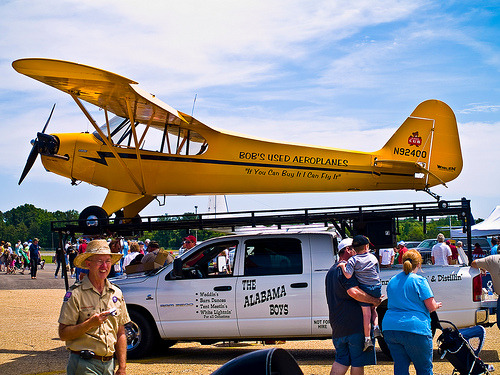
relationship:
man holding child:
[324, 236, 385, 375] [337, 235, 383, 351]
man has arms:
[324, 236, 385, 375] [347, 288, 385, 307]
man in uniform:
[58, 238, 133, 375] [59, 276, 131, 359]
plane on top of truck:
[11, 58, 462, 228] [106, 227, 490, 360]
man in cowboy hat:
[58, 238, 133, 375] [72, 238, 123, 271]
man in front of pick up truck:
[58, 238, 133, 375] [106, 227, 490, 360]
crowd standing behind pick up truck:
[53, 234, 203, 277] [106, 227, 490, 360]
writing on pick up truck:
[239, 277, 289, 317] [106, 227, 490, 360]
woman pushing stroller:
[382, 249, 443, 374] [437, 316, 496, 375]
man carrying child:
[324, 236, 385, 375] [337, 235, 383, 351]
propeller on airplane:
[15, 101, 58, 184] [11, 58, 462, 228]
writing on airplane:
[237, 151, 350, 169] [11, 58, 462, 228]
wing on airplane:
[12, 58, 222, 135] [11, 58, 462, 228]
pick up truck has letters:
[106, 227, 490, 360] [239, 277, 289, 317]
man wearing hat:
[58, 238, 133, 375] [72, 238, 123, 271]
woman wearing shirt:
[382, 249, 443, 374] [381, 269, 435, 336]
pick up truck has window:
[106, 227, 490, 360] [163, 239, 239, 281]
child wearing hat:
[337, 235, 383, 351] [352, 233, 375, 250]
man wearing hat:
[180, 235, 204, 267] [184, 233, 197, 243]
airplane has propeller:
[11, 58, 462, 228] [15, 101, 58, 184]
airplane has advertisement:
[11, 58, 462, 228] [238, 148, 350, 180]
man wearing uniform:
[58, 238, 133, 375] [59, 276, 131, 359]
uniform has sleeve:
[59, 276, 131, 359] [58, 289, 81, 326]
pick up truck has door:
[106, 227, 490, 360] [154, 236, 240, 342]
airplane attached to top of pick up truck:
[11, 58, 462, 228] [106, 227, 490, 360]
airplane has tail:
[11, 58, 462, 228] [371, 100, 462, 191]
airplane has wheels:
[11, 58, 462, 228] [76, 205, 143, 230]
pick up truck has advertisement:
[106, 227, 490, 360] [158, 277, 290, 320]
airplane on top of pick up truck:
[11, 58, 462, 228] [106, 227, 490, 360]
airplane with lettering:
[11, 58, 462, 228] [237, 151, 350, 169]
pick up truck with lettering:
[106, 227, 490, 360] [239, 277, 289, 317]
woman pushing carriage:
[382, 249, 443, 374] [437, 316, 496, 375]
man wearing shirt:
[58, 238, 133, 375] [59, 276, 131, 359]